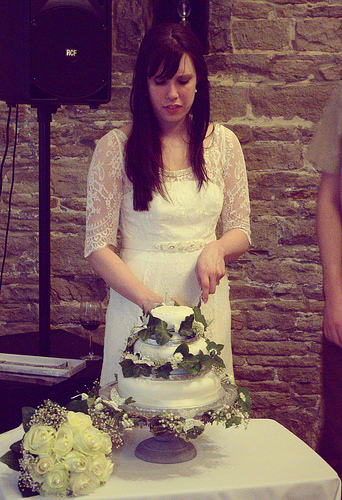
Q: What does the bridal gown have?
A: It has lace.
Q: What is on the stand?
A: The cake.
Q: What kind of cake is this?
A: Three layer wedding cake.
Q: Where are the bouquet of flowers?
A: On the table.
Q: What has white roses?
A: The bouquet.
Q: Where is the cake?
A: On the table with tablecloth.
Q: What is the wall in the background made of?
A: Bricks.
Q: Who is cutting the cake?
A: The bride.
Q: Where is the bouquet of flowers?
A: On the table.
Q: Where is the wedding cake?
A: On the table.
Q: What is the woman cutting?
A: Cake.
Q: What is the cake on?
A: Stand.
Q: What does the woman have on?
A: Wedding dress.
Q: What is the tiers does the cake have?
A: Three tires.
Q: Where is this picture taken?
A: A wedding.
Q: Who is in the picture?
A: A bride.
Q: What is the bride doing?
A: Cutting cake.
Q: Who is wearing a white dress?
A: The woman with dark hair.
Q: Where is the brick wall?
A: Behind the woman cutting a cake.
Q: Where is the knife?
A: In the woman's hand.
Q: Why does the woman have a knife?
A: She is cutting a cake.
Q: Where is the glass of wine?
A: Behind the woman.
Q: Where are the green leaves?
A: On the cake.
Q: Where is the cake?
A: In front of the woman.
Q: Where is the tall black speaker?
A: On the left side.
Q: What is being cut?
A: Cake.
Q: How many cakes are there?
A: One.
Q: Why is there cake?
A: Celebration.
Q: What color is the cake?
A: White.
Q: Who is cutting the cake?
A: Girl.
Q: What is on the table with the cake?
A: Flowers.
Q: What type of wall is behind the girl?
A: Brick.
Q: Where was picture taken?
A: At a wedding reception.